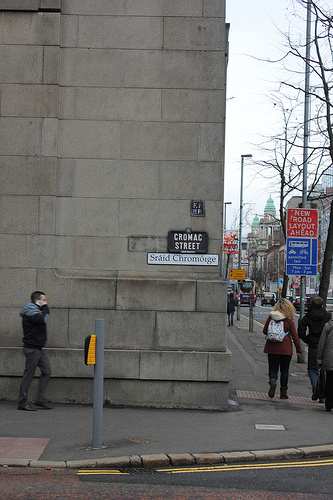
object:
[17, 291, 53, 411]
man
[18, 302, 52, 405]
clothing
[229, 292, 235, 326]
person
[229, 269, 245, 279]
sign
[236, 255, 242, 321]
pole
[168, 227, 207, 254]
street sign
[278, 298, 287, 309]
hair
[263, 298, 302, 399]
cat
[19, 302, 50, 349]
hoodie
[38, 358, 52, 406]
leg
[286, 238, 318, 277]
sign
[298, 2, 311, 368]
pole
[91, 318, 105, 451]
pole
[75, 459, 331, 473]
lines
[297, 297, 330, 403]
man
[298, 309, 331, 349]
coat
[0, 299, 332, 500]
street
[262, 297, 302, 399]
person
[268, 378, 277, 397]
feet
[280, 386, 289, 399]
feet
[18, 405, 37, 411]
feet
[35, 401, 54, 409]
feet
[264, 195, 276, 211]
blue building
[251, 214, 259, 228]
blue building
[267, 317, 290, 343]
backpack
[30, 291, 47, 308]
head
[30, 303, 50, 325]
arm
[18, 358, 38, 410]
leg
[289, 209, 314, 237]
letters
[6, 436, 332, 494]
street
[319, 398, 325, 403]
feet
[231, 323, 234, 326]
feet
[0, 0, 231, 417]
building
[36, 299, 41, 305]
phone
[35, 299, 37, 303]
ear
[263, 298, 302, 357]
coat